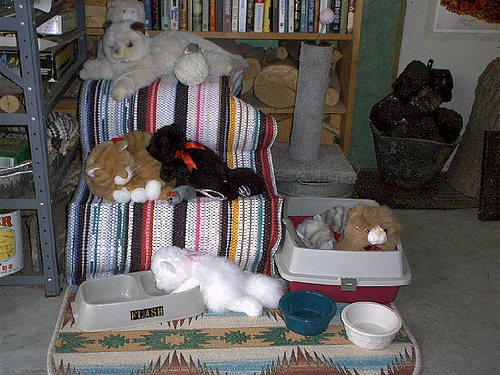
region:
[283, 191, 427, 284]
teddy bear in litter box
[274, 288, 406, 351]
two dog bowls on Indian print rug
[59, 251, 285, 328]
white stuffed animal lying face down in dog dish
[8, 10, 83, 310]
corner of metal shelf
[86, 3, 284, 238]
stuffed animals lying on striped rug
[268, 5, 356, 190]
gray cat scratching post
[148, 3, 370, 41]
books lined on wooden shelf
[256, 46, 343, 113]
cut logs on wooden shelf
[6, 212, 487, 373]
light gray floor with rug on top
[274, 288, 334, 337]
dark blue dog food bowl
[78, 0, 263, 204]
Three stuffed animals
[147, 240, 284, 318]
Fluffy white cat with pink ribbon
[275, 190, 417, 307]
Two stuffed cats in a litter box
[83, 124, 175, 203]
Orange cat with white paws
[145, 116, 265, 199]
Black stuffed cat with red bow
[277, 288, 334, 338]
Blue plastic cat dish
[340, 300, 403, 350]
White plastic food dish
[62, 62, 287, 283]
Striped blanket on a chair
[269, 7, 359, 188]
Grey carpet scratching post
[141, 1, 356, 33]
Books on a wood shelf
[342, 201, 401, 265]
a brown stuffed animal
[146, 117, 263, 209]
a brown stuffed animal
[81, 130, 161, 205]
a brown stuffed cat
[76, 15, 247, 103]
a large white stuffed animal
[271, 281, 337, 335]
a green water bowl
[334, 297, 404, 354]
a white water bowl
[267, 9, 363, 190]
a carpet scratching post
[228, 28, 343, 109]
cut firewood on a shelf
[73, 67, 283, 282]
a multi colored blanket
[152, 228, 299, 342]
a white teddy bear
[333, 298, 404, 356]
a white food bowl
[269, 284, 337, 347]
a blue food bowl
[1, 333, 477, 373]
a colorful towel on floor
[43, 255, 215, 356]
a tan food dish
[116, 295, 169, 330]
wrods written on dish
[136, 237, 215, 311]
a bear laying in dish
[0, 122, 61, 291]
a steel grey shelf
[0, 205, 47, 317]
a red and yellow white can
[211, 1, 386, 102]
books and wood on a shelf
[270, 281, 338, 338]
A blue, plastic bowl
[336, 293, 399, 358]
A white, plastic bowl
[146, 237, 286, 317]
A white, furry stuffed animal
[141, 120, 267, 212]
A black, stuffed animal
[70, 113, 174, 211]
A brown and white stuffed cat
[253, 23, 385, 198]
A cat's post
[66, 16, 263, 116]
A beige, stuffed animal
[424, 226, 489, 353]
Carpet on the ground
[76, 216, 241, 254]
A colorful, stripped rug